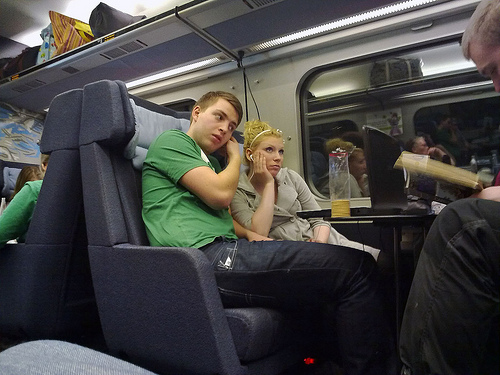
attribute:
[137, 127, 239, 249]
shirt — green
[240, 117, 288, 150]
hair — brown, blonde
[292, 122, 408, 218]
laptop — black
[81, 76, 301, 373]
seat — blue, navy blue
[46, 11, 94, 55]
bag — yellow, red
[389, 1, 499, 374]
man — reading, sitting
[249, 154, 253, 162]
ear bud — for listening, white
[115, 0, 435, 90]
overhead light — fluorescent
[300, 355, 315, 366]
light — red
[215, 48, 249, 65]
electrical outlet — white